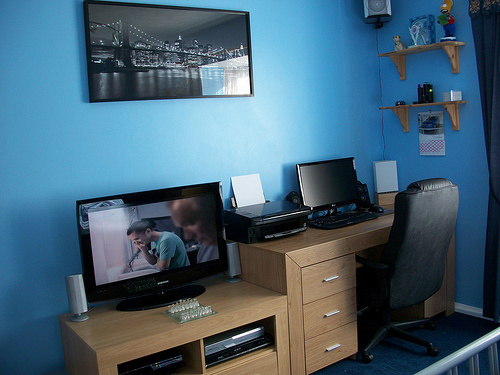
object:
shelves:
[377, 40, 464, 132]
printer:
[224, 198, 313, 244]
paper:
[231, 174, 266, 208]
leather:
[381, 178, 460, 311]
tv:
[75, 181, 229, 302]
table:
[59, 275, 291, 374]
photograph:
[84, 1, 255, 103]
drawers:
[300, 252, 357, 375]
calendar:
[417, 111, 445, 156]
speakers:
[65, 242, 242, 323]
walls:
[0, 0, 385, 374]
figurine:
[437, 0, 457, 43]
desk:
[238, 205, 455, 375]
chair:
[355, 178, 459, 365]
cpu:
[296, 157, 361, 212]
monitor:
[301, 160, 358, 207]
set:
[162, 298, 217, 325]